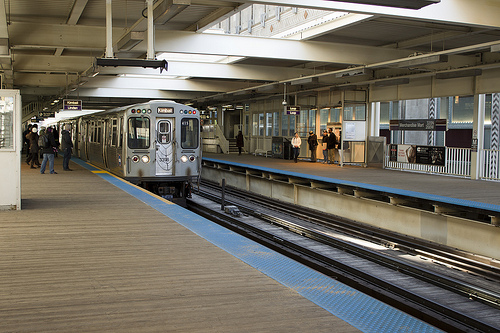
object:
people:
[284, 127, 345, 163]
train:
[74, 98, 217, 181]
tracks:
[247, 225, 304, 254]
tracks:
[284, 205, 345, 240]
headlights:
[130, 149, 198, 166]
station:
[19, 9, 490, 327]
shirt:
[288, 137, 304, 148]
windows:
[247, 113, 322, 133]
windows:
[81, 121, 120, 150]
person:
[58, 119, 74, 180]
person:
[39, 122, 56, 175]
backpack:
[36, 133, 51, 150]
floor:
[0, 171, 446, 332]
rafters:
[170, 29, 310, 79]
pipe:
[217, 63, 459, 94]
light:
[279, 99, 298, 109]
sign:
[61, 98, 91, 115]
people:
[27, 122, 82, 177]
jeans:
[42, 153, 58, 175]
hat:
[30, 127, 41, 134]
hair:
[27, 131, 39, 142]